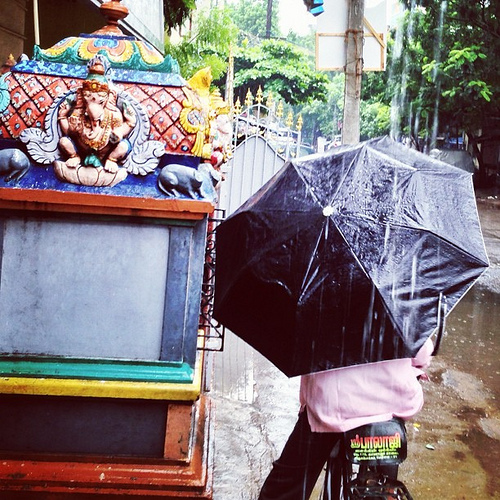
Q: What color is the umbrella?
A: Black.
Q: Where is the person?
A: On motorbike.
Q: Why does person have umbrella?
A: It's raining.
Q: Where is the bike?
A: On road.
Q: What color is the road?
A: Brown.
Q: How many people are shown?
A: One.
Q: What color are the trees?
A: Green.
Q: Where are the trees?
A: On sidewalk.